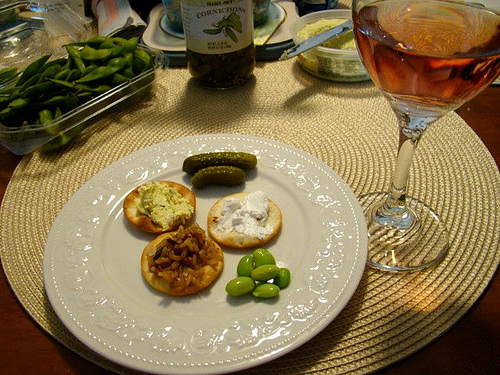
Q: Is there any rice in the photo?
A: Yes, there is rice.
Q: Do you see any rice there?
A: Yes, there is rice.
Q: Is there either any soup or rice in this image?
A: Yes, there is rice.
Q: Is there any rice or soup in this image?
A: Yes, there is rice.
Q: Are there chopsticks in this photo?
A: No, there are no chopsticks.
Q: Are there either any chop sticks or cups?
A: No, there are no chop sticks or cups.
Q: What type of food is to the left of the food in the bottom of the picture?
A: The food is rice.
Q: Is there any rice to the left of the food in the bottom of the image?
A: Yes, there is rice to the left of the food.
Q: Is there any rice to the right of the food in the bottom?
A: No, the rice is to the left of the food.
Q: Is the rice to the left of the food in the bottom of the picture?
A: Yes, the rice is to the left of the food.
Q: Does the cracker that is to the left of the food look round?
A: Yes, the cracker is round.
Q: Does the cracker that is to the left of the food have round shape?
A: Yes, the cracker is round.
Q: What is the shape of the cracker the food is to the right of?
A: The cracker is round.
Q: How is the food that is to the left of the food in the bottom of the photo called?
A: The food is a cracker.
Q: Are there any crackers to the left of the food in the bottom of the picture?
A: Yes, there is a cracker to the left of the food.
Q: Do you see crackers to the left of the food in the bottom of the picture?
A: Yes, there is a cracker to the left of the food.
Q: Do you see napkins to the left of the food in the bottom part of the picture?
A: No, there is a cracker to the left of the food.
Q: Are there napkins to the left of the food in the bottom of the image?
A: No, there is a cracker to the left of the food.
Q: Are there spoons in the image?
A: No, there are no spoons.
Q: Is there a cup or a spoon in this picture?
A: No, there are no spoons or cups.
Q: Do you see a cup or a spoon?
A: No, there are no spoons or cups.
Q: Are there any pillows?
A: No, there are no pillows.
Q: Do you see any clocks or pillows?
A: No, there are no pillows or clocks.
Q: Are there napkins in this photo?
A: No, there are no napkins.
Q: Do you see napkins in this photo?
A: No, there are no napkins.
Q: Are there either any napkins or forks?
A: No, there are no napkins or forks.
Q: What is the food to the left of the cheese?
A: The food is crackers.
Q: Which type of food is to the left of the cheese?
A: The food is crackers.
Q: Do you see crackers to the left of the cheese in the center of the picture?
A: Yes, there are crackers to the left of the cheese.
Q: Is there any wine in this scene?
A: Yes, there is wine.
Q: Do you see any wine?
A: Yes, there is wine.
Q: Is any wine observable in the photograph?
A: Yes, there is wine.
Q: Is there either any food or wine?
A: Yes, there is wine.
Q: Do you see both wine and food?
A: Yes, there are both wine and food.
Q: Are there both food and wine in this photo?
A: Yes, there are both wine and food.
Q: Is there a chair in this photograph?
A: No, there are no chairs.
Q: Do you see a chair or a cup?
A: No, there are no chairs or cups.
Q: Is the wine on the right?
A: Yes, the wine is on the right of the image.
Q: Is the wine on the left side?
A: No, the wine is on the right of the image.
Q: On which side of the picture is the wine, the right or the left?
A: The wine is on the right of the image.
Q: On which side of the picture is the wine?
A: The wine is on the right of the image.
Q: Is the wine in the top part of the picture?
A: Yes, the wine is in the top of the image.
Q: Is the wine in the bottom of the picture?
A: No, the wine is in the top of the image.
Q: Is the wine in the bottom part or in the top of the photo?
A: The wine is in the top of the image.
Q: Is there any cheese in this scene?
A: Yes, there is cheese.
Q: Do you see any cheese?
A: Yes, there is cheese.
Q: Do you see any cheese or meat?
A: Yes, there is cheese.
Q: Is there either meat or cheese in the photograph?
A: Yes, there is cheese.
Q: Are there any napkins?
A: No, there are no napkins.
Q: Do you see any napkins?
A: No, there are no napkins.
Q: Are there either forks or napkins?
A: No, there are no napkins or forks.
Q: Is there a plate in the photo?
A: Yes, there is a plate.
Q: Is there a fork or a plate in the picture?
A: Yes, there is a plate.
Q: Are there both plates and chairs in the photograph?
A: No, there is a plate but no chairs.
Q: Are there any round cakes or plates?
A: Yes, there is a round plate.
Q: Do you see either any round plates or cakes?
A: Yes, there is a round plate.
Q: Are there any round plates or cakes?
A: Yes, there is a round plate.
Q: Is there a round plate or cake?
A: Yes, there is a round plate.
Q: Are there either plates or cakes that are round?
A: Yes, the plate is round.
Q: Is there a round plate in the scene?
A: Yes, there is a round plate.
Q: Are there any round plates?
A: Yes, there is a round plate.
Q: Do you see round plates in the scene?
A: Yes, there is a round plate.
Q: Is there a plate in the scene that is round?
A: Yes, there is a plate that is round.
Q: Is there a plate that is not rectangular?
A: Yes, there is a round plate.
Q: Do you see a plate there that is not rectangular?
A: Yes, there is a round plate.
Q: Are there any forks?
A: No, there are no forks.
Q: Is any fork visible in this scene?
A: No, there are no forks.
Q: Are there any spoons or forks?
A: No, there are no forks or spoons.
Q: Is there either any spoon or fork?
A: No, there are no forks or spoons.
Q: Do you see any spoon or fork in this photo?
A: No, there are no forks or spoons.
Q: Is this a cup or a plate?
A: This is a plate.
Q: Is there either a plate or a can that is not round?
A: No, there is a plate but it is round.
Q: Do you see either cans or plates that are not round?
A: No, there is a plate but it is round.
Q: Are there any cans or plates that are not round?
A: No, there is a plate but it is round.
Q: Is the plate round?
A: Yes, the plate is round.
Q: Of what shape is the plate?
A: The plate is round.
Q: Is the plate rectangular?
A: No, the plate is round.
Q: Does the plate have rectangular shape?
A: No, the plate is round.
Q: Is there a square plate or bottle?
A: No, there is a plate but it is round.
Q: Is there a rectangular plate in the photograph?
A: No, there is a plate but it is round.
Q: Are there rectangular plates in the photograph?
A: No, there is a plate but it is round.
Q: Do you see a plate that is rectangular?
A: No, there is a plate but it is round.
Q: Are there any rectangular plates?
A: No, there is a plate but it is round.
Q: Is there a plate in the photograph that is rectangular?
A: No, there is a plate but it is round.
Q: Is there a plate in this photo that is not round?
A: No, there is a plate but it is round.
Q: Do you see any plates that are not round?
A: No, there is a plate but it is round.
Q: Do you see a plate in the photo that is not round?
A: No, there is a plate but it is round.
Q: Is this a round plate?
A: Yes, this is a round plate.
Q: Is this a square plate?
A: No, this is a round plate.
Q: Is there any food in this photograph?
A: Yes, there is food.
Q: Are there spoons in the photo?
A: No, there are no spoons.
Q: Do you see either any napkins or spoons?
A: No, there are no spoons or napkins.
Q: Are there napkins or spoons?
A: No, there are no spoons or napkins.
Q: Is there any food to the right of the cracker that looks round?
A: Yes, there is food to the right of the cracker.